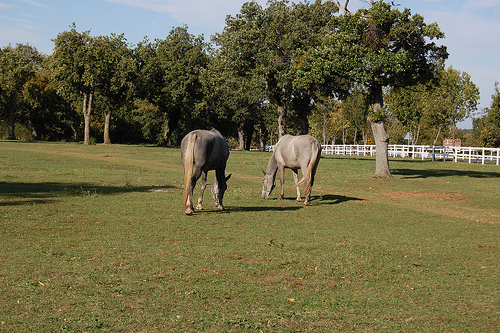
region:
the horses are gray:
[181, 123, 326, 209]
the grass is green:
[205, 236, 363, 319]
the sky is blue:
[31, 15, 148, 47]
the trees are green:
[288, 20, 441, 85]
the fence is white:
[410, 135, 497, 182]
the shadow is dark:
[5, 170, 172, 203]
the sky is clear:
[1, 0, 184, 26]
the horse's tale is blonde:
[183, 133, 209, 198]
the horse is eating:
[251, 136, 323, 214]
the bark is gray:
[370, 123, 394, 178]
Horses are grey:
[162, 111, 336, 228]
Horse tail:
[296, 134, 328, 203]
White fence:
[326, 134, 498, 164]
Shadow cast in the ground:
[7, 159, 181, 224]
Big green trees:
[8, 0, 484, 142]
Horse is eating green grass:
[163, 111, 240, 224]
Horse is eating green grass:
[249, 125, 332, 210]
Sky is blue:
[0, 0, 499, 92]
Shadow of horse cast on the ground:
[283, 181, 370, 212]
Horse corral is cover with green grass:
[5, 139, 495, 332]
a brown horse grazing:
[164, 118, 244, 226]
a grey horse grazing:
[245, 121, 342, 227]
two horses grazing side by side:
[161, 107, 347, 233]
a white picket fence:
[395, 137, 498, 182]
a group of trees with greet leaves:
[5, 40, 175, 150]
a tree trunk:
[359, 112, 406, 189]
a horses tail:
[178, 130, 200, 213]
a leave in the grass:
[263, 280, 318, 318]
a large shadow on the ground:
[0, 157, 180, 218]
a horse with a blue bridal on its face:
[253, 161, 278, 208]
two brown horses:
[155, 112, 358, 225]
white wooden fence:
[397, 127, 498, 162]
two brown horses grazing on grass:
[157, 100, 360, 242]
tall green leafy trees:
[13, 7, 420, 144]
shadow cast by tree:
[387, 157, 499, 186]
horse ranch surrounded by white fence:
[43, 7, 478, 311]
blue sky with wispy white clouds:
[111, 3, 239, 34]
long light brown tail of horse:
[168, 130, 200, 212]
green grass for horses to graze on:
[28, 217, 317, 323]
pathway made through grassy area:
[322, 178, 499, 230]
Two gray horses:
[174, 115, 329, 226]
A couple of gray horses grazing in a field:
[167, 120, 329, 218]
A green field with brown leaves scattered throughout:
[4, 132, 494, 330]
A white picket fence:
[235, 141, 499, 168]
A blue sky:
[2, 2, 499, 120]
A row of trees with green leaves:
[0, 14, 498, 191]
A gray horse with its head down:
[252, 130, 328, 215]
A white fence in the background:
[247, 136, 498, 163]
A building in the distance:
[443, 134, 462, 153]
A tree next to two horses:
[295, 1, 452, 192]